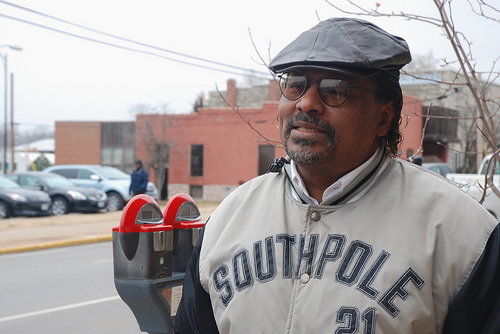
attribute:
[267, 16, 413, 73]
hat — black, dark colored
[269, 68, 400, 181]
man — black, smiling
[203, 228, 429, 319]
letters — blue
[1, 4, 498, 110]
sky — white, clear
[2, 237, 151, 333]
street — gray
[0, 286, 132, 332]
line — white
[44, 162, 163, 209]
car — parked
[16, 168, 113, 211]
car — parked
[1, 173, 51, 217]
car — parked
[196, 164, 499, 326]
jacket — gray, black, white, blue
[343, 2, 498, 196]
tree — bare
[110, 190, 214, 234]
meter — red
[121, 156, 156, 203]
person — walking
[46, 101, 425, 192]
building — large, brick, red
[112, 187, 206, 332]
meters — black, red